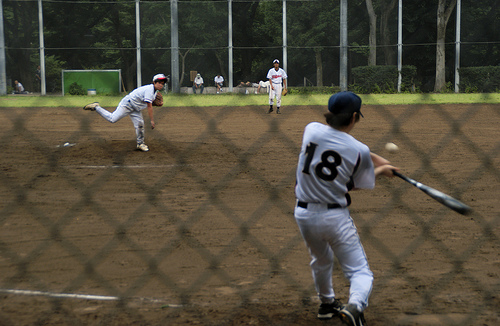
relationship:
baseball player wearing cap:
[83, 73, 168, 152] [147, 71, 171, 90]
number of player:
[300, 137, 351, 194] [256, 73, 395, 262]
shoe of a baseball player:
[333, 294, 378, 324] [293, 90, 399, 326]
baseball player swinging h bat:
[293, 90, 399, 326] [391, 153, 480, 223]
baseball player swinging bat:
[293, 90, 399, 326] [389, 170, 473, 216]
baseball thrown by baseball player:
[385, 140, 401, 152] [83, 73, 168, 152]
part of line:
[82, 293, 101, 297] [3, 288, 194, 309]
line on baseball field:
[3, 288, 194, 309] [2, 90, 496, 321]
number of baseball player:
[300, 140, 340, 183] [293, 90, 400, 322]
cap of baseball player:
[323, 90, 364, 117] [293, 90, 399, 326]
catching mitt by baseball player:
[152, 94, 162, 104] [83, 73, 168, 152]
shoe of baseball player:
[341, 300, 369, 323] [293, 90, 399, 326]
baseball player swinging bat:
[293, 90, 400, 322] [393, 166, 472, 216]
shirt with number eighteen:
[296, 120, 375, 200] [300, 140, 341, 181]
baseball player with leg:
[83, 73, 168, 152] [80, 100, 125, 119]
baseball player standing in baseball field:
[268, 61, 288, 110] [0, 90, 500, 321]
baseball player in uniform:
[293, 90, 400, 322] [292, 122, 376, 307]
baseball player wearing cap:
[293, 90, 400, 322] [327, 90, 364, 118]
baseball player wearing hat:
[83, 71, 170, 149] [153, 73, 167, 83]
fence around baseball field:
[1, 40, 496, 91] [0, 90, 500, 321]